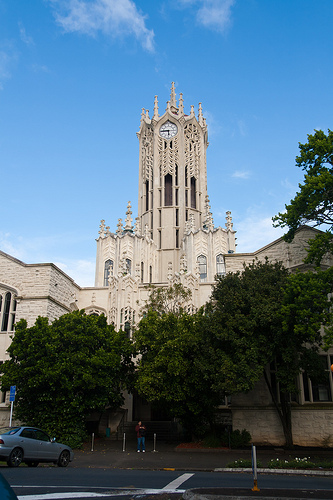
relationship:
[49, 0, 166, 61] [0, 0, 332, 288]
cloud in sky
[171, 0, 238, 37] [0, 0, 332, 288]
cloud in sky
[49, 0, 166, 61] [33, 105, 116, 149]
cloud in sky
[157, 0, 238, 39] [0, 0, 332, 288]
cloud in sky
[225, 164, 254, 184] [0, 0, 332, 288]
cloud in sky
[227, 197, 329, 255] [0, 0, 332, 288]
cloud in sky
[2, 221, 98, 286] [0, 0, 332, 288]
cloud in sky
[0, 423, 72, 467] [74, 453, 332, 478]
car parked near curb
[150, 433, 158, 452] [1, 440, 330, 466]
pole in pavement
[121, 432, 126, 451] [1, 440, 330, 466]
pole in pavement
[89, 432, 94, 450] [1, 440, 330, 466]
pole in pavement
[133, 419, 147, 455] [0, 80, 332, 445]
person standing outside of building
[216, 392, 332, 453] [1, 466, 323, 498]
wall facing street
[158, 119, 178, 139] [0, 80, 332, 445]
clock on top of building